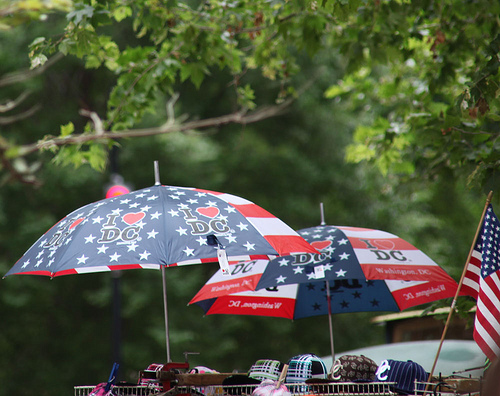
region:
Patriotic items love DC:
[10, 164, 499, 333]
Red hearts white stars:
[92, 180, 228, 277]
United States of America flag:
[432, 189, 499, 394]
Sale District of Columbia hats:
[69, 354, 451, 392]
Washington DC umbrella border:
[339, 222, 454, 286]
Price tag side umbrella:
[199, 229, 239, 290]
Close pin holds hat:
[263, 361, 295, 393]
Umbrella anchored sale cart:
[114, 152, 211, 373]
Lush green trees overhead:
[7, 6, 499, 152]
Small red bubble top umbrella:
[97, 176, 157, 232]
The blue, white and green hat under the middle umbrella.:
[276, 345, 331, 387]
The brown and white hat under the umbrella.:
[322, 352, 374, 381]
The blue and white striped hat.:
[374, 353, 426, 394]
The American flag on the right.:
[471, 206, 498, 353]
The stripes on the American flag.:
[468, 249, 498, 348]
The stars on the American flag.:
[477, 206, 499, 269]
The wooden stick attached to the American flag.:
[439, 182, 494, 387]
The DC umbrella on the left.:
[12, 183, 307, 277]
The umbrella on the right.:
[190, 197, 466, 325]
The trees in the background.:
[2, 116, 495, 301]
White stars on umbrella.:
[61, 192, 175, 302]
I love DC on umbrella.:
[101, 200, 159, 270]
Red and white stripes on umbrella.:
[202, 156, 287, 268]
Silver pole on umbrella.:
[141, 246, 209, 383]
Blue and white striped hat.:
[373, 345, 408, 382]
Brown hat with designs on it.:
[331, 337, 351, 377]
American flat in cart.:
[456, 209, 493, 277]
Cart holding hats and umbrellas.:
[97, 349, 229, 393]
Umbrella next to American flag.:
[271, 190, 398, 328]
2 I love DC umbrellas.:
[54, 112, 433, 354]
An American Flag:
[458, 194, 498, 376]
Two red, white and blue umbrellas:
[7, 188, 460, 309]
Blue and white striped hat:
[365, 354, 432, 388]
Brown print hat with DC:
[315, 353, 373, 385]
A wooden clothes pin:
[276, 364, 291, 386]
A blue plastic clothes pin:
[107, 357, 121, 386]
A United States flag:
[462, 198, 499, 361]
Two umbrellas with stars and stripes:
[7, 182, 462, 307]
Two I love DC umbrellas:
[14, 184, 454, 307]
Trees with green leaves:
[33, 3, 495, 167]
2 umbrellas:
[15, 153, 457, 363]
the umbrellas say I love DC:
[26, 174, 495, 375]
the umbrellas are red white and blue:
[32, 184, 478, 361]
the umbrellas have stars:
[42, 162, 403, 344]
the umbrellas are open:
[32, 156, 489, 348]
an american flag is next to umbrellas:
[423, 194, 495, 391]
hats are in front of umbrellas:
[145, 353, 437, 394]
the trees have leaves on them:
[22, 0, 460, 151]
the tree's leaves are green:
[60, 1, 460, 176]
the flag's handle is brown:
[387, 239, 497, 382]